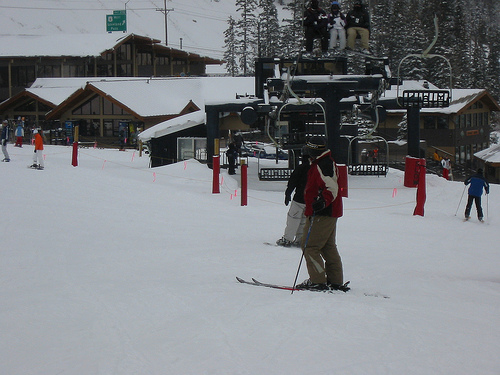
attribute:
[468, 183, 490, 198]
coat — blue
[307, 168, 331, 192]
coat — red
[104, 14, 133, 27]
sign — green, highway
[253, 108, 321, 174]
lift — ski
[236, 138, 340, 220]
person — wearing, skiing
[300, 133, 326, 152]
hat — white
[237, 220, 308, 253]
ski — snow, resort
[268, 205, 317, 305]
pole — ski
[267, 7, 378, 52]
people — riding, skiing, standing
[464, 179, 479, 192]
jacket — blue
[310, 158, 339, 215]
jacket — red